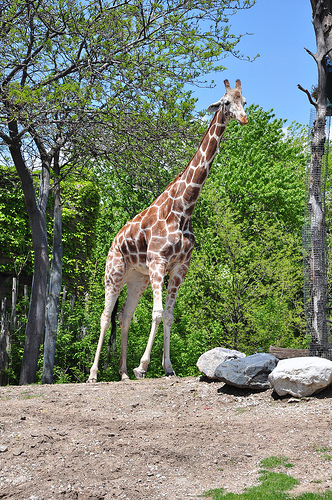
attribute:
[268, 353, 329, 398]
rock — similar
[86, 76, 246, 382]
giraffe — long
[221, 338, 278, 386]
stone — black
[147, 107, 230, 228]
giraffe's neck — long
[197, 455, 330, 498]
grass — green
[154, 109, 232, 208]
neck — long 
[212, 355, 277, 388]
rock — similar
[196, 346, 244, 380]
rock — similar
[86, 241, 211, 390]
legs — long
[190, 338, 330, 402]
rocks — three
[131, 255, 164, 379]
leg — long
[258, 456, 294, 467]
grass — green 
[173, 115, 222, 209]
neck — long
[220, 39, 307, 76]
sky — blue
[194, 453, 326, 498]
grass patch — green 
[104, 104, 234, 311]
spots — dark